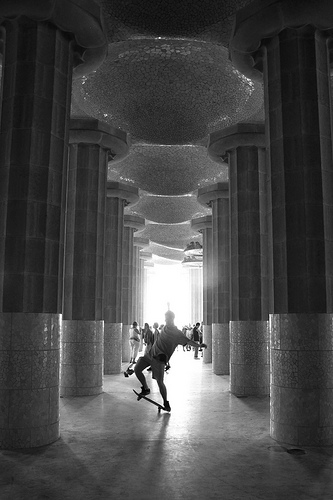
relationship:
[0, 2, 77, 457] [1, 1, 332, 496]
column of building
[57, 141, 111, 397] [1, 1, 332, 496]
column of building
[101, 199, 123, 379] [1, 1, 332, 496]
column of building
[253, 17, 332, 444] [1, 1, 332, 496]
column of building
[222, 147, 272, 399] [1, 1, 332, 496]
column of building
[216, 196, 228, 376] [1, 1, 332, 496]
column of building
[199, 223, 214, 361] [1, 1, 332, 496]
column of building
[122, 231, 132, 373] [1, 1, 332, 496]
column of building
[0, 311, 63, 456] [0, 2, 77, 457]
bottom of column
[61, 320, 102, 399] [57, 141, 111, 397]
bottom of column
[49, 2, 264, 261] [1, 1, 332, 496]
ceiling of building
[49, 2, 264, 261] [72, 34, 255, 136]
ceiling has design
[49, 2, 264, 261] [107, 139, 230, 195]
ceiling has design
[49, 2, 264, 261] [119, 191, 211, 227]
ceiling has design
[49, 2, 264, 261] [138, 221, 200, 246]
ceiling has design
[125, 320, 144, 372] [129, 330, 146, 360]
woman wearing cloths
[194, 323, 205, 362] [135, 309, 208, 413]
person behind man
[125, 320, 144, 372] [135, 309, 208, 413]
woman behind man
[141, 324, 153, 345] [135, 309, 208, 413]
person behind man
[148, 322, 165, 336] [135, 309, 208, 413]
person behind man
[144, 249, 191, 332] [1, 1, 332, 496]
outdoor of building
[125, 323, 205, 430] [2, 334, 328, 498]
light on floor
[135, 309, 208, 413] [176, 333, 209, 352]
man has arm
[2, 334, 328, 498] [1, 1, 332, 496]
floor of building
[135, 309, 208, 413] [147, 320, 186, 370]
man in shirt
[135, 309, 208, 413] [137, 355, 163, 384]
man in shorts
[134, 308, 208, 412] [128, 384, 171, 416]
skater making tricks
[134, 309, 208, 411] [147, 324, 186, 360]
skater wears shirt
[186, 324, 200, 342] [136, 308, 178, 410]
people behind skater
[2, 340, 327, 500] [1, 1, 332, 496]
floor of building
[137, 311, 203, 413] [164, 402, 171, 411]
man wearing shoe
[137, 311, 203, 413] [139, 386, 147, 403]
man wearing shoe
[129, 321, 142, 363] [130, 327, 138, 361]
woman wearing outfit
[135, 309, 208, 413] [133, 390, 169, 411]
man riding skateboard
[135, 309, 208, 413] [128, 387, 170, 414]
man losing his balance on skateboard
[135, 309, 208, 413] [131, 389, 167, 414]
man about to fall off skateboard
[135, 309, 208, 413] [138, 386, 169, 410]
man wearing shoes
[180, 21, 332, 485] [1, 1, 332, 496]
columns of building